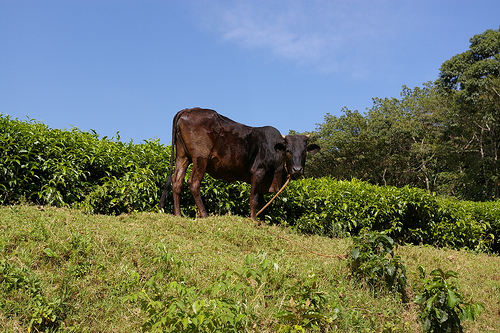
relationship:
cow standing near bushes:
[160, 107, 321, 225] [124, 157, 325, 212]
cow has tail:
[160, 99, 324, 223] [169, 106, 182, 173]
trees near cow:
[343, 100, 457, 187] [165, 100, 298, 225]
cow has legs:
[160, 107, 321, 225] [160, 160, 222, 224]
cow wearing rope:
[160, 107, 321, 225] [249, 155, 291, 229]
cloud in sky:
[211, 26, 358, 85] [0, 23, 482, 151]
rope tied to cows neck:
[252, 157, 292, 219] [280, 143, 292, 180]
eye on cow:
[283, 146, 292, 155] [160, 107, 321, 225]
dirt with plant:
[201, 222, 291, 260] [271, 192, 341, 234]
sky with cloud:
[1, 2, 499, 157] [0, 0, 499, 152]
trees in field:
[371, 107, 450, 177] [5, 200, 484, 329]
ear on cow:
[306, 137, 321, 153] [160, 107, 321, 225]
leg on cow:
[168, 162, 219, 219] [168, 106, 320, 220]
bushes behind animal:
[2, 114, 484, 254] [169, 105, 318, 218]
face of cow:
[272, 133, 319, 175] [160, 107, 321, 225]